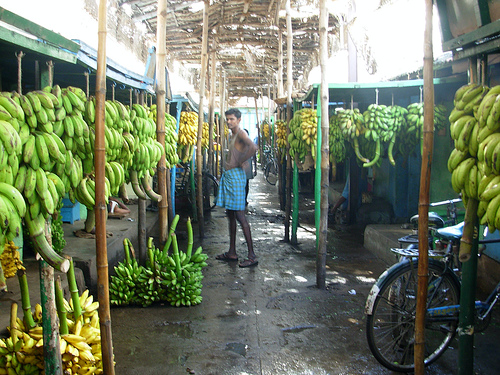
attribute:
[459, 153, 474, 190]
banana — green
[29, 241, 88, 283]
brown stem — green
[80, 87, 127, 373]
bamboo stick — tall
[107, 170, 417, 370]
ground — brown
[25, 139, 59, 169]
banana — green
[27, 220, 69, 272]
stem — green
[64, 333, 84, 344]
banana — yellow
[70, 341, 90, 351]
banana — yellow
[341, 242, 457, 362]
tire — black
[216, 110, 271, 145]
hair — black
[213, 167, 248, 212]
shorts — blue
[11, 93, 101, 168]
bananas — large